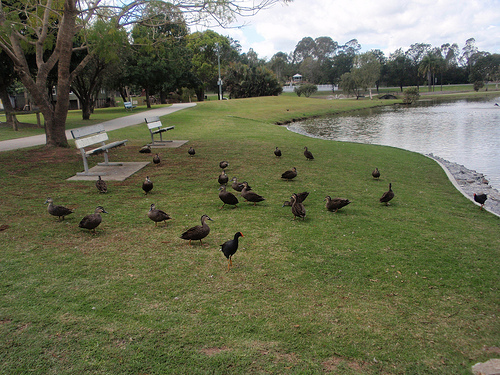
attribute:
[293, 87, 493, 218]
water — calm, wavy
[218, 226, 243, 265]
duck — black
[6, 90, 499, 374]
grass — green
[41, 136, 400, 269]
ducks — black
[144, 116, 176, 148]
bench — white, gray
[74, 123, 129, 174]
bench — white, gray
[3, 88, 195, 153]
walking path — clear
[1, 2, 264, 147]
tree — brown, leafless, bare, large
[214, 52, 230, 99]
light pole — steel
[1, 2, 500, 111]
trees — green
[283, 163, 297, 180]
duck — black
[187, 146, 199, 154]
duck — black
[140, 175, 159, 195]
duck — black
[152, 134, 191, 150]
slab — concrete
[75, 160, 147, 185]
slab — concrete